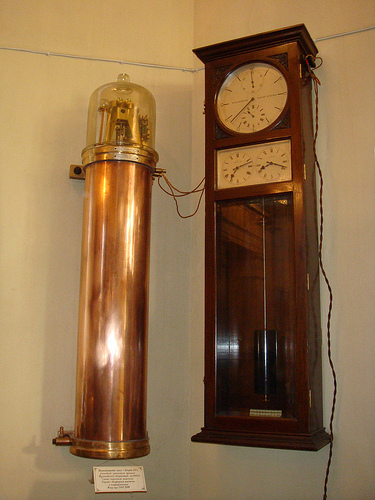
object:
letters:
[101, 471, 137, 482]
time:
[215, 57, 290, 135]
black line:
[265, 118, 269, 123]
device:
[217, 61, 289, 135]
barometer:
[52, 73, 160, 459]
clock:
[190, 21, 334, 452]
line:
[224, 105, 247, 118]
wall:
[0, 2, 371, 489]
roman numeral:
[275, 107, 282, 111]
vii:
[263, 173, 266, 177]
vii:
[228, 178, 232, 182]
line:
[262, 67, 270, 78]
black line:
[274, 76, 282, 83]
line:
[249, 69, 253, 88]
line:
[229, 72, 242, 83]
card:
[91, 465, 147, 492]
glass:
[86, 72, 157, 152]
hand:
[231, 96, 255, 122]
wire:
[158, 173, 206, 220]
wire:
[304, 53, 336, 500]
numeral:
[281, 153, 286, 157]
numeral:
[283, 159, 289, 163]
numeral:
[277, 172, 281, 176]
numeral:
[229, 176, 234, 183]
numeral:
[224, 88, 232, 93]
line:
[275, 90, 287, 96]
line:
[235, 116, 243, 130]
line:
[220, 84, 231, 94]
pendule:
[261, 199, 269, 407]